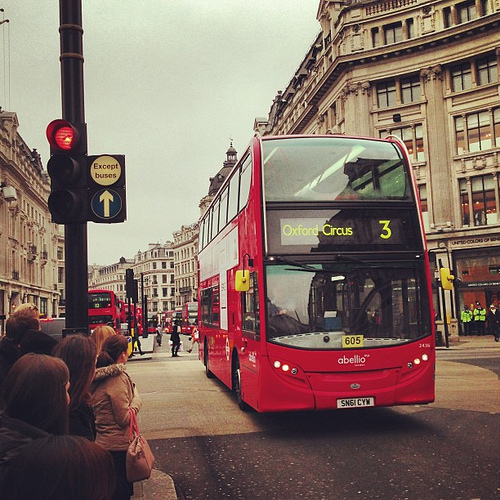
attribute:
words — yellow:
[283, 213, 394, 235]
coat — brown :
[85, 363, 148, 459]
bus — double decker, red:
[184, 123, 453, 433]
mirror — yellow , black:
[223, 257, 256, 296]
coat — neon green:
[458, 305, 475, 335]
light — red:
[50, 113, 78, 154]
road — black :
[115, 322, 496, 498]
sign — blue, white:
[87, 184, 127, 223]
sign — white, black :
[87, 145, 125, 190]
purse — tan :
[116, 431, 163, 489]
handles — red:
[120, 395, 150, 437]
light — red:
[54, 127, 76, 149]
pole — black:
[56, 2, 97, 350]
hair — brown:
[95, 334, 131, 366]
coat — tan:
[85, 359, 145, 457]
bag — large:
[125, 406, 160, 485]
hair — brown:
[0, 350, 70, 429]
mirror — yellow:
[232, 265, 252, 292]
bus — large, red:
[194, 131, 443, 420]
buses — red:
[89, 282, 198, 340]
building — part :
[1, 98, 74, 337]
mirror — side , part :
[223, 261, 251, 297]